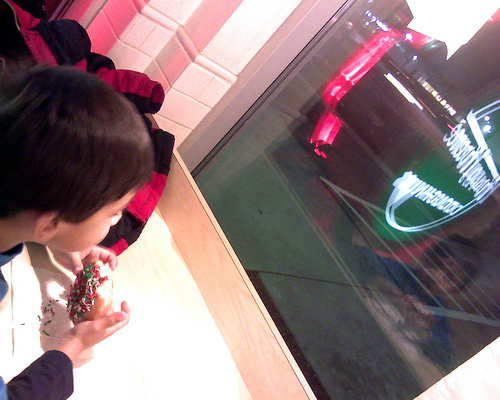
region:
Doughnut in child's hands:
[61, 258, 113, 324]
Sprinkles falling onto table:
[36, 292, 59, 340]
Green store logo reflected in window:
[369, 85, 496, 247]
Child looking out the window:
[0, 51, 157, 398]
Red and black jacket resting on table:
[0, 0, 175, 264]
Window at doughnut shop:
[174, 0, 494, 398]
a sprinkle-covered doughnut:
[56, 259, 113, 321]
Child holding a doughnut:
[0, 66, 158, 397]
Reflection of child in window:
[325, 234, 481, 372]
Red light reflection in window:
[306, 9, 433, 156]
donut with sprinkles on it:
[52, 256, 131, 333]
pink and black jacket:
[1, 0, 180, 280]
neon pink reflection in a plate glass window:
[172, 2, 498, 399]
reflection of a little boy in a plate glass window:
[177, 2, 497, 399]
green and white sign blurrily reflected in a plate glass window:
[181, 0, 498, 399]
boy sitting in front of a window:
[1, 0, 498, 399]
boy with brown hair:
[2, 49, 192, 398]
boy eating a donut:
[0, 52, 190, 399]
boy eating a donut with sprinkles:
[2, 47, 171, 399]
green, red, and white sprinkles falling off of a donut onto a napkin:
[5, 242, 130, 374]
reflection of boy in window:
[355, 137, 477, 370]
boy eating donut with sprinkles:
[13, 67, 198, 392]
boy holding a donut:
[15, 44, 137, 372]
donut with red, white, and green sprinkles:
[46, 256, 196, 386]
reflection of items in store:
[318, 19, 498, 304]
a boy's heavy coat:
[22, 17, 208, 275]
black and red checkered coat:
[16, 19, 197, 306]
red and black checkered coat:
[16, 6, 251, 338]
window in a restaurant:
[121, 1, 499, 378]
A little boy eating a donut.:
[31, 105, 128, 342]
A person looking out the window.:
[179, 59, 497, 369]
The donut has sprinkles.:
[58, 272, 88, 318]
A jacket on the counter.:
[53, 12, 159, 99]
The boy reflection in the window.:
[270, 154, 476, 339]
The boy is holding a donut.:
[43, 229, 132, 347]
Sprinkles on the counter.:
[18, 281, 68, 343]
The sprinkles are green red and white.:
[76, 267, 98, 307]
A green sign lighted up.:
[415, 112, 498, 247]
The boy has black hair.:
[38, 87, 93, 169]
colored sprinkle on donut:
[78, 302, 89, 310]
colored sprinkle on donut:
[85, 285, 100, 292]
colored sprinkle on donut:
[85, 275, 101, 290]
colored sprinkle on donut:
[80, 260, 95, 275]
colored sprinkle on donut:
[72, 275, 82, 285]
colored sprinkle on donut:
[62, 286, 72, 301]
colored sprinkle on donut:
[65, 295, 76, 311]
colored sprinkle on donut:
[66, 275, 76, 291]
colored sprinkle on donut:
[80, 305, 90, 310]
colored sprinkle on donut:
[75, 307, 85, 322]